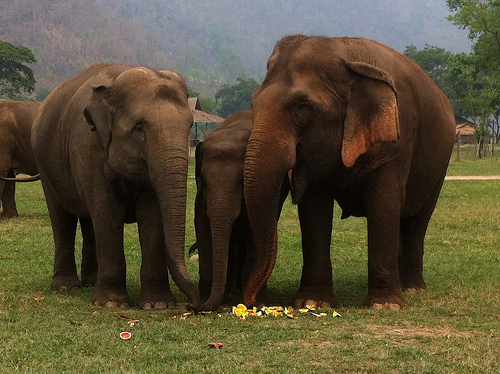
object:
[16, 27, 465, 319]
family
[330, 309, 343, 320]
oranges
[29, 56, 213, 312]
elephant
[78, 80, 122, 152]
small ears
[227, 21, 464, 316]
large elephant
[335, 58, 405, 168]
elephant ear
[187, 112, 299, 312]
baby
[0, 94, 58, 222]
elephant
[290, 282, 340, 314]
elephant feet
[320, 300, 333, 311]
toenails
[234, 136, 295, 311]
elephant trunk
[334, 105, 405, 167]
edge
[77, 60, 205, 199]
two bigger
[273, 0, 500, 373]
right side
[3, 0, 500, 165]
background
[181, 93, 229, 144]
small hut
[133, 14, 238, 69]
visible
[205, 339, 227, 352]
red circular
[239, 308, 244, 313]
yellow debris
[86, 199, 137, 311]
leg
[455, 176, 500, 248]
large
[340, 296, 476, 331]
area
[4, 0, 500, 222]
large area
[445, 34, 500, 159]
many trees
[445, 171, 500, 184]
sidewalk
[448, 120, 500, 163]
shelter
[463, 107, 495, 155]
people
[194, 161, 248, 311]
trunks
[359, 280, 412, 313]
feet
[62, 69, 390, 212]
facing forward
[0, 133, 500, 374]
grass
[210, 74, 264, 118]
palm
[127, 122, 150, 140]
eye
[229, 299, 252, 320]
fruit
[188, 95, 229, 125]
roof